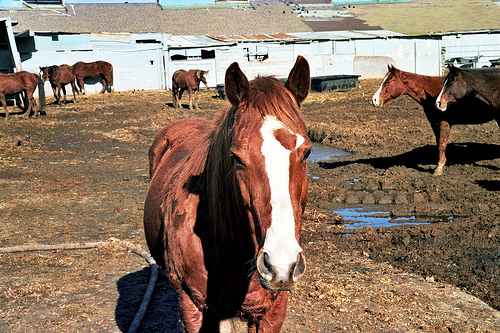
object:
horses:
[0, 60, 499, 331]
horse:
[142, 55, 314, 333]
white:
[257, 113, 307, 291]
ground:
[0, 78, 499, 332]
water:
[300, 131, 470, 239]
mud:
[1, 79, 498, 333]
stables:
[0, 0, 498, 99]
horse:
[435, 64, 500, 124]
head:
[225, 55, 315, 292]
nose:
[257, 251, 306, 284]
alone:
[143, 55, 312, 332]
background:
[0, 0, 499, 111]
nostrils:
[259, 249, 308, 283]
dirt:
[0, 78, 499, 332]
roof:
[0, 0, 498, 45]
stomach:
[143, 221, 168, 274]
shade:
[313, 142, 499, 172]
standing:
[0, 58, 499, 332]